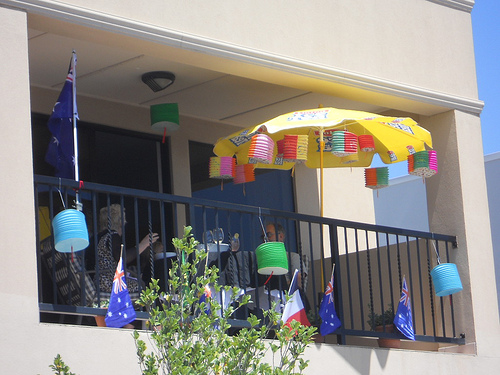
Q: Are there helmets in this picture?
A: No, there are no helmets.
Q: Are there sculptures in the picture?
A: No, there are no sculptures.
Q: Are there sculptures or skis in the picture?
A: No, there are no sculptures or skis.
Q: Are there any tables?
A: Yes, there is a table.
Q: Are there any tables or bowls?
A: Yes, there is a table.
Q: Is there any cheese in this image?
A: No, there is no cheese.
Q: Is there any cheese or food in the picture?
A: No, there are no cheese or food.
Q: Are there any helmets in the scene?
A: No, there are no helmets.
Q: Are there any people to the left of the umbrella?
A: Yes, there is a person to the left of the umbrella.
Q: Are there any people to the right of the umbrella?
A: No, the person is to the left of the umbrella.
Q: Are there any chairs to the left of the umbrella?
A: No, there is a person to the left of the umbrella.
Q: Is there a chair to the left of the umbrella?
A: No, there is a person to the left of the umbrella.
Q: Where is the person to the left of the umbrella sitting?
A: The person is sitting at the table.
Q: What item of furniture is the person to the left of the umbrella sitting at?
A: The person is sitting at the table.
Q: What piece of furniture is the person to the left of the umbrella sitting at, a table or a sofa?
A: The person is sitting at a table.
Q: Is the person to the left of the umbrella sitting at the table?
A: Yes, the person is sitting at the table.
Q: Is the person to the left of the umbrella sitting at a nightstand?
A: No, the person is sitting at the table.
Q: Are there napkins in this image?
A: No, there are no napkins.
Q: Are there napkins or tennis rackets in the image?
A: No, there are no napkins or tennis rackets.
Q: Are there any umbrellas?
A: Yes, there is an umbrella.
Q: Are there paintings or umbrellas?
A: Yes, there is an umbrella.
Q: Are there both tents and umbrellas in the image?
A: No, there is an umbrella but no tents.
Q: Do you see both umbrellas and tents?
A: No, there is an umbrella but no tents.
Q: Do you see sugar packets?
A: No, there are no sugar packets.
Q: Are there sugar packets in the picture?
A: No, there are no sugar packets.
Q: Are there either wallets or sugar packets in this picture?
A: No, there are no sugar packets or wallets.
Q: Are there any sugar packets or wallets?
A: No, there are no sugar packets or wallets.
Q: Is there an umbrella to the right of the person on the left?
A: Yes, there is an umbrella to the right of the person.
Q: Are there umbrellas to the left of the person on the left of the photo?
A: No, the umbrella is to the right of the person.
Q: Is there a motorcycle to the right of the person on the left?
A: No, there is an umbrella to the right of the person.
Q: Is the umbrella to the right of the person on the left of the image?
A: Yes, the umbrella is to the right of the person.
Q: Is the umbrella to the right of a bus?
A: No, the umbrella is to the right of the person.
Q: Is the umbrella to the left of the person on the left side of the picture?
A: No, the umbrella is to the right of the person.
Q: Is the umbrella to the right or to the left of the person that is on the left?
A: The umbrella is to the right of the person.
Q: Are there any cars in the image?
A: No, there are no cars.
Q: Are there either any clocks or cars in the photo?
A: No, there are no cars or clocks.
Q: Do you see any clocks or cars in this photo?
A: No, there are no cars or clocks.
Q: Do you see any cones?
A: No, there are no cones.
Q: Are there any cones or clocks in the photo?
A: No, there are no cones or clocks.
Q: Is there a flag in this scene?
A: Yes, there is a flag.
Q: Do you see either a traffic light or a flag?
A: Yes, there is a flag.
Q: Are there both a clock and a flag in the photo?
A: No, there is a flag but no clocks.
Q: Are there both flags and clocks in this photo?
A: No, there is a flag but no clocks.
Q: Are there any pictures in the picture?
A: No, there are no pictures.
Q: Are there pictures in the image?
A: No, there are no pictures.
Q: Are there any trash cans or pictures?
A: No, there are no pictures or trash cans.